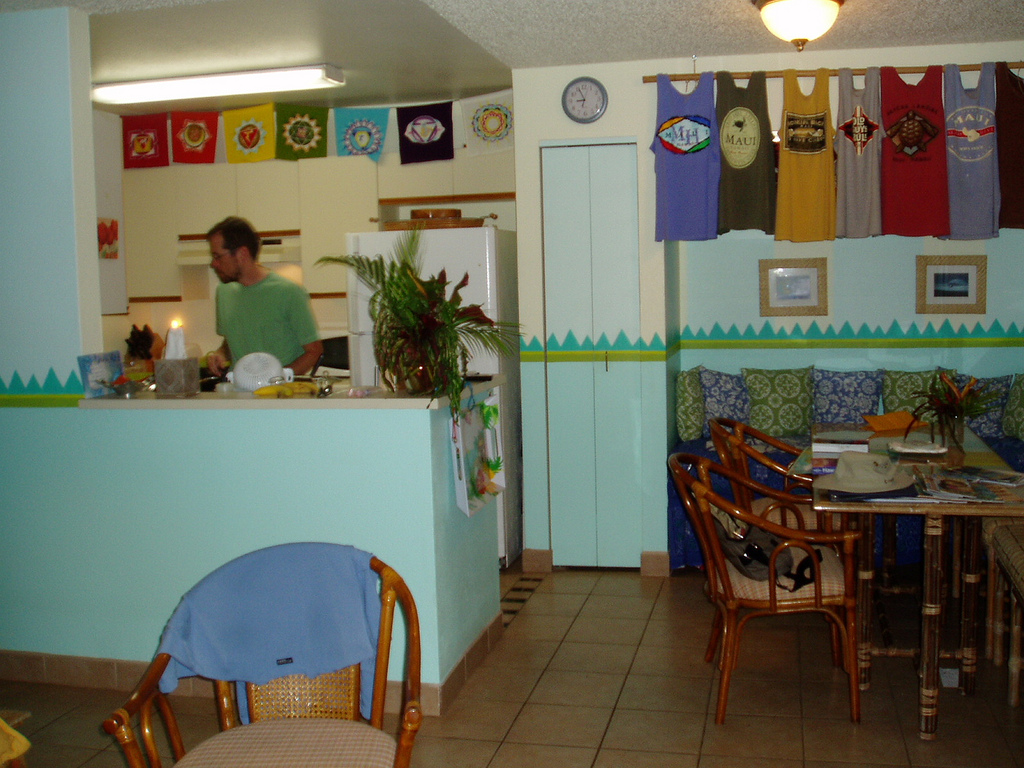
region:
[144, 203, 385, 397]
Man wearing green shirt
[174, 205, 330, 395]
Man wearing glasses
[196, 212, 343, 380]
Man standing in kitchen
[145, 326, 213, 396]
Box of tissues on counter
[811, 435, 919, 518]
Hat on table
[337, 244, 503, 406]
Potted plant on the counter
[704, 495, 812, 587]
Backpack on the chair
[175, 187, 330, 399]
this is a man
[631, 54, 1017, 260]
a row of shirts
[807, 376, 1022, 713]
a brown dining table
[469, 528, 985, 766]
tile on the floor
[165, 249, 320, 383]
man wearing a green shirt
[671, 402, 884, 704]
a set of chairs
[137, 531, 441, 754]
cloth on the chair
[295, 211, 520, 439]
plant on the counter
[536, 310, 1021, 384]
trim on the wall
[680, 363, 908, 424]
blue and green pillows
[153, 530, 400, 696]
blue shirt draped over the chair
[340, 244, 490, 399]
fern plant on the counter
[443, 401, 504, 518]
picture on the side of the counter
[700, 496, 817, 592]
pocketbook in the chair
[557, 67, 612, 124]
clock on the wall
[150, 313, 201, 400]
box of tissues on the counter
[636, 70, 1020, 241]
shirts hanging on a bar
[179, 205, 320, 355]
man behind the counter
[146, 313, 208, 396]
box with tissues on the counter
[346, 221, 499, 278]
fridge next to the wall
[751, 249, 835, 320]
picture on the wall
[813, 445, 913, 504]
hat on the table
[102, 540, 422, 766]
the blue fabric on the chair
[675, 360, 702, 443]
the pillow is green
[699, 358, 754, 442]
the pillow is blue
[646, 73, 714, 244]
the shirt is purple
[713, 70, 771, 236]
the shirt say's MAUI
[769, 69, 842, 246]
the shirt is yellow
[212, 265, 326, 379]
the shirt is green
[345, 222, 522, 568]
the refrigerator is white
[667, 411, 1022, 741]
the chairs around the table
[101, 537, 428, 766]
a blue shirt hanging over the back of a chair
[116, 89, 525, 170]
collection of colorful flags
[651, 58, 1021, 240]
collection of colorful tee shirts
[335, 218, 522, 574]
white refrigerator in kitchen area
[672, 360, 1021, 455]
row of colorful decorative pillows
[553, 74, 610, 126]
round clock affixed to wall above door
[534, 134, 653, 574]
door to utility closet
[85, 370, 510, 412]
bar top to counter separating kitchen from living area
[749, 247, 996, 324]
two framed items affixed to wall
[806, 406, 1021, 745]
booth-style dining table near wall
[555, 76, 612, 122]
a small blue and white clock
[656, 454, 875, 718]
a brown dining chair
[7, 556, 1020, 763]
a tiled floor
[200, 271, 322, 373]
a man's short sleeve green shirt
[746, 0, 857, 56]
a small ceiling light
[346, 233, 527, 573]
a white refrigerator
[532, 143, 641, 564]
a small door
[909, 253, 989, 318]
a small picture frame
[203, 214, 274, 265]
a man's short cut hair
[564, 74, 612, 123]
clock hanging on the wall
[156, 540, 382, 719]
blue shirt drapped over the chair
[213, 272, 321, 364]
green tee shirt man is wearing